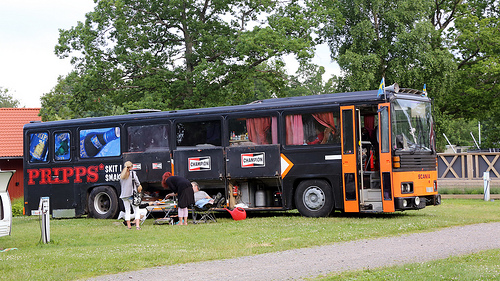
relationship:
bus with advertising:
[21, 73, 441, 219] [237, 146, 268, 170]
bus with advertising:
[21, 73, 441, 219] [184, 149, 214, 174]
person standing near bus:
[118, 160, 143, 230] [21, 73, 441, 219]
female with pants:
[161, 171, 196, 225] [175, 205, 188, 217]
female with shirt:
[161, 171, 196, 225] [166, 173, 193, 194]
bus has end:
[21, 73, 441, 219] [382, 92, 451, 212]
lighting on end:
[403, 198, 410, 208] [382, 92, 451, 212]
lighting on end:
[411, 192, 420, 207] [382, 92, 451, 212]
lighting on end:
[405, 180, 413, 192] [382, 92, 451, 212]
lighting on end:
[398, 180, 407, 191] [382, 92, 451, 212]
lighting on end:
[433, 179, 438, 189] [382, 92, 451, 212]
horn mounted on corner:
[379, 80, 397, 96] [365, 90, 403, 127]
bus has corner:
[21, 73, 441, 219] [365, 90, 403, 127]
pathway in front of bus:
[74, 217, 499, 279] [21, 73, 441, 219]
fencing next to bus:
[436, 150, 484, 197] [21, 73, 441, 219]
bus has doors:
[21, 73, 441, 219] [339, 103, 393, 213]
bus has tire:
[21, 73, 441, 219] [88, 186, 120, 219]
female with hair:
[156, 154, 196, 227] [159, 170, 172, 181]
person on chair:
[192, 185, 218, 213] [187, 204, 219, 224]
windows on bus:
[27, 107, 345, 154] [0, 51, 448, 236]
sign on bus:
[34, 157, 121, 204] [21, 73, 441, 219]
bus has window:
[21, 73, 441, 219] [226, 110, 278, 145]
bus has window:
[21, 73, 441, 219] [171, 122, 219, 146]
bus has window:
[21, 73, 441, 219] [118, 119, 173, 155]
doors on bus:
[339, 103, 393, 213] [21, 73, 441, 219]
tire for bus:
[77, 179, 129, 224] [22, 90, 448, 214]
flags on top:
[376, 72, 431, 102] [380, 89, 442, 107]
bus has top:
[14, 74, 449, 224] [380, 89, 442, 107]